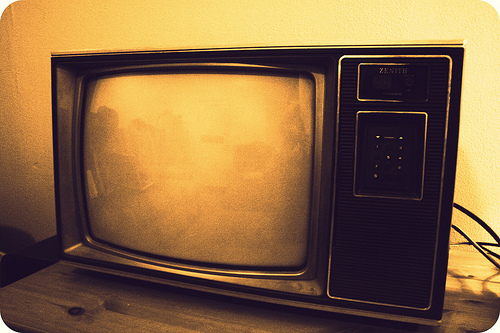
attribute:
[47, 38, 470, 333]
television — existing, old style, old, off, showing reflection, in storage room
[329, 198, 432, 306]
speaker — black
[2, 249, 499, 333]
table — existing, wood, dark, wooden, brown, smooth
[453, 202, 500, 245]
cable — existing, dark, black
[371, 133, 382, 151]
button — existing, black, white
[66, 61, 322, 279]
monitor — existing, glass, small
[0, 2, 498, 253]
wall — bare, orange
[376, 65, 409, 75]
word — zenith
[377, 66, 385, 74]
letter — z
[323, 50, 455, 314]
trim — silver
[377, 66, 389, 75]
letters — ze